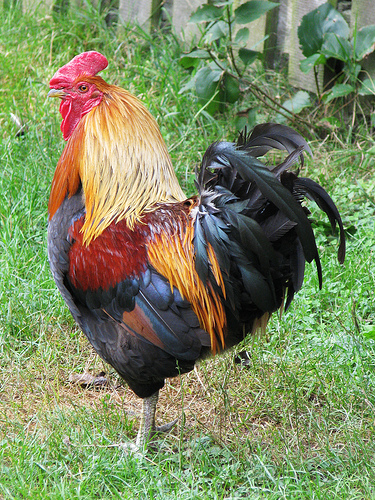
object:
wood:
[273, 1, 322, 86]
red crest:
[42, 49, 109, 89]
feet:
[103, 417, 196, 461]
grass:
[0, 0, 375, 500]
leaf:
[319, 32, 352, 65]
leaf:
[349, 22, 374, 66]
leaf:
[175, 66, 226, 112]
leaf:
[230, 0, 283, 24]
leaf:
[177, 48, 216, 71]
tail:
[181, 113, 355, 334]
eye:
[71, 80, 95, 103]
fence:
[0, 1, 372, 131]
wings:
[68, 206, 234, 365]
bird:
[46, 49, 346, 470]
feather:
[189, 123, 343, 356]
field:
[0, 0, 375, 500]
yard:
[0, 0, 375, 500]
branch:
[200, 42, 319, 131]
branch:
[225, 5, 244, 78]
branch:
[312, 62, 321, 100]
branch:
[347, 81, 358, 145]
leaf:
[191, 59, 229, 99]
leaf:
[246, 102, 260, 125]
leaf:
[188, 3, 223, 23]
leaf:
[296, 2, 351, 55]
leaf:
[324, 79, 356, 102]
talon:
[152, 420, 181, 449]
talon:
[110, 439, 150, 471]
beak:
[46, 88, 66, 99]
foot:
[152, 420, 178, 441]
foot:
[109, 439, 147, 468]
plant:
[182, 1, 375, 145]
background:
[0, 0, 374, 500]